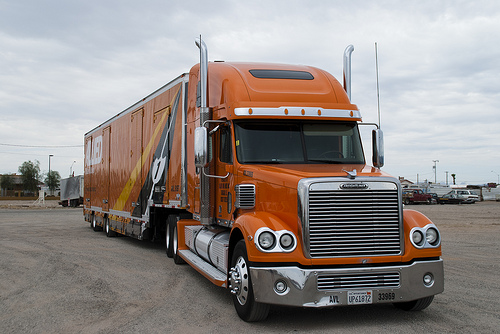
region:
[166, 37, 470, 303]
front of the truck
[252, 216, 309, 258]
light on front of truck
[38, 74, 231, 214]
side of the truck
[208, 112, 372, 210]
window on front of truck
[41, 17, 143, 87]
sky above the land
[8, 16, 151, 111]
clouds in the sky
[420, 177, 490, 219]
cars in the distance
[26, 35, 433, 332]
one large truck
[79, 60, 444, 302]
The truck is orange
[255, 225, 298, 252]
Circle headlights on the truck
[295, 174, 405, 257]
The truck's grill is silver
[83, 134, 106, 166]
The truck's logo is Allied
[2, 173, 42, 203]
Brown building in the background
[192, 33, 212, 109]
The exhaust pipes are metal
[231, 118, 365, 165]
Front windshield of the truck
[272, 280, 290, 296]
The trucks's foglights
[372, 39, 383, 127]
The antenna of the truck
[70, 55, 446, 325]
an orange semi truck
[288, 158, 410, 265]
a chrome grill on a semi truck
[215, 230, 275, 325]
a black tire on a truck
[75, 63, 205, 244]
a trailer behind a semi truck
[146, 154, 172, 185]
route one white sign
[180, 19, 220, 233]
a chrome exhaust pipe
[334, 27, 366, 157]
a chrome exhaust pipe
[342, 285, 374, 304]
a white license plate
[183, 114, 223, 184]
a chrome side mirror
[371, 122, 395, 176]
a chrome side mirror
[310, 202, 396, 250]
grill of the truck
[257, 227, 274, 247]
a headlight on the truck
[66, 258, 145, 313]
the road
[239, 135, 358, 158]
a windsheild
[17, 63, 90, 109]
the clouds are white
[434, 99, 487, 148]
clouds in the sky are white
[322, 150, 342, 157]
a steering wheel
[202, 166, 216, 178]
a handle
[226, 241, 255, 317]
front tire on the truck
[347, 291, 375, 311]
the license plate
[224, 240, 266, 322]
black wheel of truck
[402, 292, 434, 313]
black wheel of truck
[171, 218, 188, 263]
black wheel of truck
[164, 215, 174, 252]
black wheel of truck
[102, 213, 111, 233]
black wheel of truck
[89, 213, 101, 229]
black wheel of truck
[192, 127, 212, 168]
chrome mirror of truck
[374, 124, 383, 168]
chrome mirror of truck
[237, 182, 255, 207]
chrome grill of truck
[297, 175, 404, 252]
chrome grill on truck